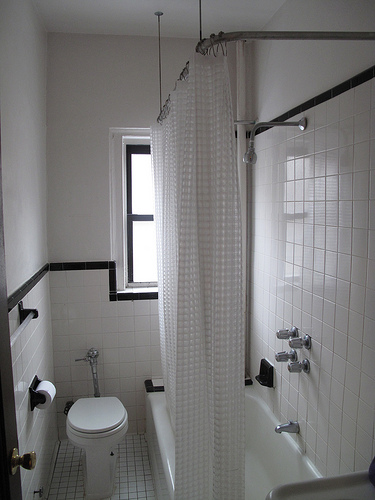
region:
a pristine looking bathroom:
[0, 1, 373, 499]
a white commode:
[66, 391, 128, 499]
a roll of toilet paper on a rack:
[34, 379, 55, 413]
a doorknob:
[11, 447, 37, 475]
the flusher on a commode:
[75, 355, 87, 363]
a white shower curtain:
[150, 58, 248, 498]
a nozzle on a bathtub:
[273, 413, 301, 441]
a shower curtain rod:
[221, 30, 374, 42]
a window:
[125, 146, 155, 288]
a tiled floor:
[123, 452, 152, 495]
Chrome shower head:
[240, 116, 315, 165]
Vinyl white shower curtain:
[140, 47, 266, 498]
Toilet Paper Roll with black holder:
[24, 370, 54, 411]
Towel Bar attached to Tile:
[3, 303, 45, 344]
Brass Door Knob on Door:
[6, 439, 43, 474]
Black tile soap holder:
[248, 353, 275, 387]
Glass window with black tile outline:
[110, 130, 155, 299]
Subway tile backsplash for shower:
[236, 176, 366, 256]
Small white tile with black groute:
[121, 450, 147, 496]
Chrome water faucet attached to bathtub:
[270, 415, 308, 446]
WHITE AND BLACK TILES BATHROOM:
[32, 29, 373, 436]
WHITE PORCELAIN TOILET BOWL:
[75, 430, 141, 498]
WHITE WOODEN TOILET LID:
[57, 387, 129, 441]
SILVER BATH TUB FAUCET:
[268, 414, 313, 432]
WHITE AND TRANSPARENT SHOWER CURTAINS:
[159, 160, 263, 491]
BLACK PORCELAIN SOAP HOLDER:
[252, 359, 280, 382]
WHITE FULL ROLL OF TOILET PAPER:
[35, 375, 59, 409]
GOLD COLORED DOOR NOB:
[6, 443, 41, 472]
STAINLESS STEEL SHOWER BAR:
[261, 459, 360, 498]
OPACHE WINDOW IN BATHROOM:
[117, 138, 170, 284]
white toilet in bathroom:
[55, 383, 140, 498]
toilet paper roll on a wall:
[20, 367, 62, 415]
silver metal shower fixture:
[285, 332, 312, 351]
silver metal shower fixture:
[273, 324, 305, 341]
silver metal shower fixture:
[280, 352, 315, 376]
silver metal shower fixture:
[269, 344, 304, 364]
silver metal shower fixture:
[266, 414, 306, 438]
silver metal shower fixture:
[232, 112, 315, 170]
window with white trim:
[98, 113, 170, 299]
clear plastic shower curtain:
[126, 100, 272, 497]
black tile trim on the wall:
[11, 256, 122, 311]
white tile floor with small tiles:
[122, 440, 154, 498]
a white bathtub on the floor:
[148, 377, 326, 492]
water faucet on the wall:
[266, 415, 303, 442]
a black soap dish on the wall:
[253, 354, 277, 387]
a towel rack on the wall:
[6, 303, 44, 345]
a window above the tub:
[105, 127, 163, 301]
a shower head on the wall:
[235, 111, 319, 166]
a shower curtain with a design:
[144, 47, 259, 499]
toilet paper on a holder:
[19, 371, 59, 410]